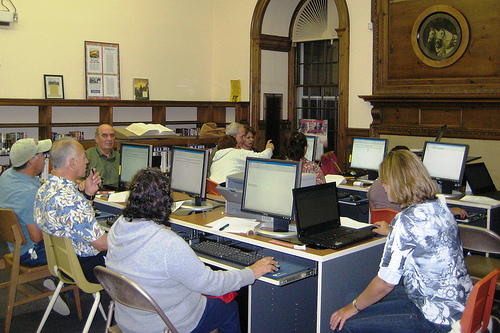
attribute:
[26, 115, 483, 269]
people — sitting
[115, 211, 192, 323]
sweater — grey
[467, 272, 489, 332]
chair — orange, gray, plastic, metal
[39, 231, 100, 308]
chair — green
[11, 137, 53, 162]
cap — green, worn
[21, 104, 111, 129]
shelf — brown, sliding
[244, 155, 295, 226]
computers — black, flat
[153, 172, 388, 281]
desks — white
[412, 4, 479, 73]
design — round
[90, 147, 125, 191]
shirt — green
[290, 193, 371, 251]
laptop — black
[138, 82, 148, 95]
picture — framed, white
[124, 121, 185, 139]
book — open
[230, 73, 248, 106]
paper — yellow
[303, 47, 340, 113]
window — dark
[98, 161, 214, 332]
woman — sitting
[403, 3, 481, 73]
frame — circular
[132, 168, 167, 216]
hair — black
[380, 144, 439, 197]
hair — blonde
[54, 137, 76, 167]
hair — grey